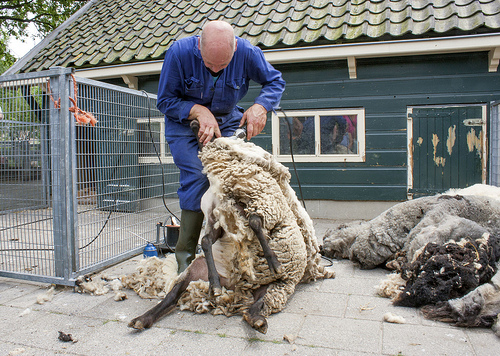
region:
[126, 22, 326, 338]
man shearing a sheep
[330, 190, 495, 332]
sheared off sheep skins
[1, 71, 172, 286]
a wire fence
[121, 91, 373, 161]
windows with cream frames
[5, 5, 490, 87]
tiled roof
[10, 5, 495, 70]
tiled roof is black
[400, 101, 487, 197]
door has painted chipped off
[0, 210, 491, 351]
stone tiled sidewalk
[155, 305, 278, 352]
grass growing in the cracks of the pavement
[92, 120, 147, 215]
door ajar inside of fenced area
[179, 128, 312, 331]
a sheep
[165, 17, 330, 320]
a man sheering a sheep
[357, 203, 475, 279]
wool from the sheep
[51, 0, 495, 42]
shingles on the building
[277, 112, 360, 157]
a window on the building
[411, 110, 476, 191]
a door to the building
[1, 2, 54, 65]
a tree behind the building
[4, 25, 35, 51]
the sky behind the tree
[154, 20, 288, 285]
a man in a blue jumpsuit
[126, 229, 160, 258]
a small blue canister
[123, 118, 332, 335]
a sheep being sheared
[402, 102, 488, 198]
a small green door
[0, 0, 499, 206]
A small green building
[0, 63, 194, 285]
a small metal pin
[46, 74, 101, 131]
some orange rope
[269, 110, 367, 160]
a window on a building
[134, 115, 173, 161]
a window on a building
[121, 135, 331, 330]
A sheep being sheared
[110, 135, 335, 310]
Fleece being sheared from this sheep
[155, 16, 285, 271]
Man shearing the sheep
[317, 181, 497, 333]
Pile of fleece from many sheared sheep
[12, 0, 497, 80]
Tile roof on the sheep barn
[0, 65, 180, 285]
A cage outside the sheep barn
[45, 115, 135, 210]
An open sheep-barn door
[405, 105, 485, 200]
A closed sheep-barn door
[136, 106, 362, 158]
Sheep-barn windows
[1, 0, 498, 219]
A sheep barn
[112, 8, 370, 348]
man sheering adult sheep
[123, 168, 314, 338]
four legs of sheep facing outward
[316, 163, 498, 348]
large pile of sheep wool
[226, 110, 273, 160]
man holding sheep shearer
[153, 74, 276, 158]
man holding head of sheep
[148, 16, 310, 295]
man wearing blue work suit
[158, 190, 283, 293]
man wearing green boots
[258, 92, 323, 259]
cord of shearing tool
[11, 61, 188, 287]
metal fence surrounding enclosure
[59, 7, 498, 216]
sheep shed is green